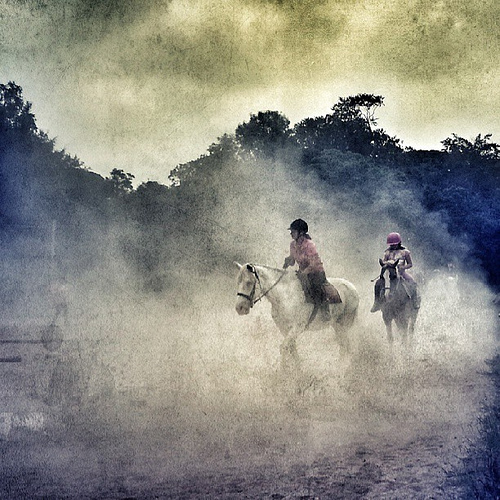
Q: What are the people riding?
A: Horses.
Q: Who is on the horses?
A: Children.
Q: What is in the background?
A: Trees.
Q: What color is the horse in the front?
A: White.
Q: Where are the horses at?
A: Dirt field.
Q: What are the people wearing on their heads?
A: Helmets.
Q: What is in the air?
A: Dust.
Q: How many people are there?
A: Two.